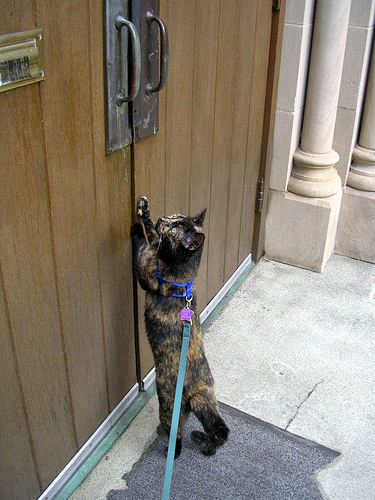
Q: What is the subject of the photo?
A: Cat.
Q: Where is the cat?
A: Doorstep.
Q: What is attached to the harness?
A: Leash.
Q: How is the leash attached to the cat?
A: Harness.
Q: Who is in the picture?
A: No one.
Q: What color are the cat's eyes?
A: Yellow.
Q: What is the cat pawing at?
A: Door.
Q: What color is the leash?
A: Blue.